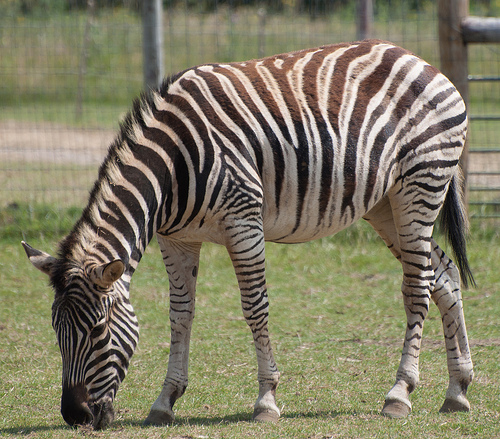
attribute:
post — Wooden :
[438, 2, 466, 80]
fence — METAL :
[5, 0, 497, 235]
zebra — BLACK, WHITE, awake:
[18, 43, 469, 428]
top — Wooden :
[457, 11, 499, 43]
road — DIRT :
[1, 116, 498, 191]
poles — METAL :
[138, 0, 165, 97]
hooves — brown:
[32, 134, 245, 431]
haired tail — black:
[454, 230, 472, 296]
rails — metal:
[16, 211, 34, 253]